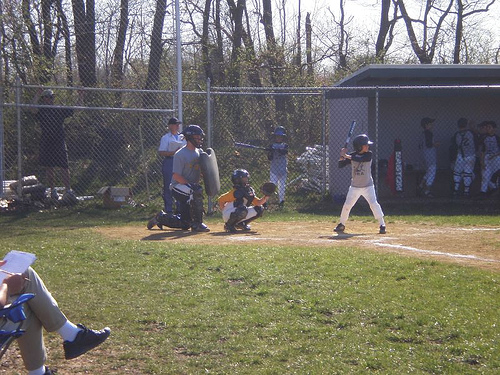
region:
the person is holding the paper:
[5, 248, 79, 318]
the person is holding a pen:
[0, 260, 64, 309]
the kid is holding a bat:
[329, 110, 399, 191]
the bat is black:
[353, 134, 383, 158]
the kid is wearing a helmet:
[334, 115, 371, 160]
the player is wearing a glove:
[227, 167, 285, 232]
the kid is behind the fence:
[245, 115, 312, 197]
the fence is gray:
[204, 85, 242, 135]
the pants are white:
[334, 176, 419, 235]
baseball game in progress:
[135, 105, 430, 262]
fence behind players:
[0, 30, 430, 250]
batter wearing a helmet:
[348, 132, 373, 148]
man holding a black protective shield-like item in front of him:
[171, 120, 221, 236]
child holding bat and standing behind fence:
[227, 115, 302, 205]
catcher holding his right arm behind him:
[215, 160, 258, 235]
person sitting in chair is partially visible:
[2, 236, 127, 372]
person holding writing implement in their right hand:
[0, 263, 35, 285]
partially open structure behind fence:
[322, 55, 497, 210]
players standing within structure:
[381, 60, 496, 204]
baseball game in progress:
[23, 22, 482, 347]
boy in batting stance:
[324, 113, 404, 249]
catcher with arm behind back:
[213, 160, 281, 240]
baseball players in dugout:
[416, 106, 496, 195]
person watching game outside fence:
[18, 81, 98, 218]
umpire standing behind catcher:
[150, 104, 192, 232]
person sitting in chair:
[7, 218, 86, 369]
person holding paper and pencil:
[2, 232, 50, 304]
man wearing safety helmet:
[177, 119, 213, 158]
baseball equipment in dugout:
[381, 138, 427, 200]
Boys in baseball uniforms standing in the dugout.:
[400, 62, 497, 207]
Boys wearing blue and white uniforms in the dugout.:
[415, 113, 496, 199]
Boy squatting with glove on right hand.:
[215, 165, 276, 226]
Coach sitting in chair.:
[0, 245, 115, 370]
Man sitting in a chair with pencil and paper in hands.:
[0, 242, 111, 372]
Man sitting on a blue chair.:
[0, 107, 280, 369]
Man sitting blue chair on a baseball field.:
[0, 225, 180, 370]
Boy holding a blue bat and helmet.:
[331, 115, 389, 239]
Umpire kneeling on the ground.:
[150, 123, 220, 231]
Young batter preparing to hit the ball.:
[335, 118, 388, 235]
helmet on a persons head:
[346, 131, 378, 157]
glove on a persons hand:
[255, 177, 280, 202]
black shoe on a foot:
[50, 316, 120, 366]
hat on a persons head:
[162, 111, 183, 131]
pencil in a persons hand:
[0, 262, 36, 282]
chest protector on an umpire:
[190, 140, 225, 201]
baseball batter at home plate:
[320, 115, 405, 251]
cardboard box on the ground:
[87, 175, 137, 215]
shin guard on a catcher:
[216, 201, 246, 236]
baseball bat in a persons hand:
[223, 135, 278, 161]